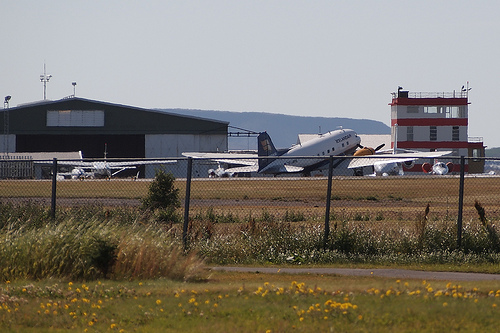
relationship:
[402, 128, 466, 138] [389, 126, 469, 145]
windows on second floor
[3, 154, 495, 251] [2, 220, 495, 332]
fence by grass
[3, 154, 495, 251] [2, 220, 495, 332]
fence near grass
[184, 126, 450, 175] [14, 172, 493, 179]
airplane on tarmac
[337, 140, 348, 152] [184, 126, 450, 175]
window on airplane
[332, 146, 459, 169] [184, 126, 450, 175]
wing on airplane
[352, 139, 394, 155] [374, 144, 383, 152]
propeller has blade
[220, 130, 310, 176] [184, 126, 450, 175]
tail of airplane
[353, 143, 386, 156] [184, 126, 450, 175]
propeller of airplane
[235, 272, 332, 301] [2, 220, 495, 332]
flowers on grass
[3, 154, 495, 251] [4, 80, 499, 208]
fence surrounding airfield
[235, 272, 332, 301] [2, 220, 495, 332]
flowers in grass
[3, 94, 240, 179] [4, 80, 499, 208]
airplane hanger at airfield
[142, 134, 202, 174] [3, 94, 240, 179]
door to airplane hanger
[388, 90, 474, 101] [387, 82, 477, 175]
fence on top of control tower